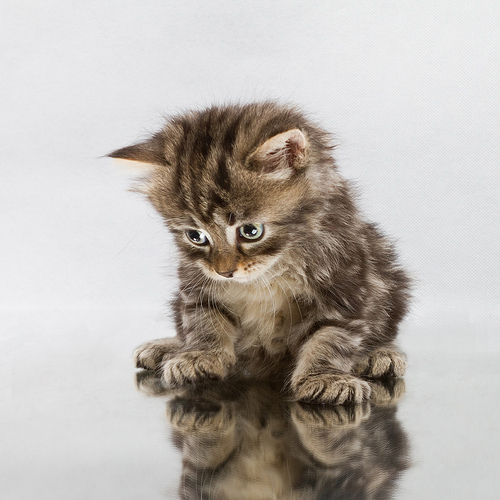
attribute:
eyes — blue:
[180, 217, 267, 248]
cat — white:
[139, 98, 369, 462]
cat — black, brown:
[107, 151, 378, 401]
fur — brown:
[160, 115, 410, 362]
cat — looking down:
[100, 99, 421, 406]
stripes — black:
[166, 111, 249, 216]